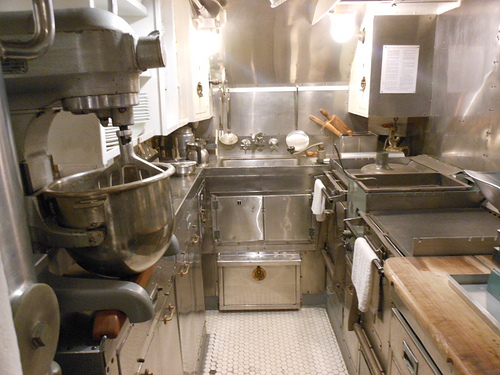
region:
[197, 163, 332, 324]
Part of a dirty kitchen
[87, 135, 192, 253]
A mixer in the kitchen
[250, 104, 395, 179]
Some silverware in the kitchen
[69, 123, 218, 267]
TO make food and drinks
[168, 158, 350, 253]
To keep things in the kitchen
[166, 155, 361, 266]
Good for storage here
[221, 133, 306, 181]
Used to wash dishes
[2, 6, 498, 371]
kitchen full of stainless steal appliances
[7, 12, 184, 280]
large stand mixer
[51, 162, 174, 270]
silver bowl of the mixer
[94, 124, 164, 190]
mixer in the silver bowl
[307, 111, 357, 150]
knife block on the counter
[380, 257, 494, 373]
wooden countertop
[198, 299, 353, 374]
white tile floor in the kitchen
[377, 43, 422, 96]
paper affixed to cabinet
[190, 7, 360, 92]
light reflecting on walls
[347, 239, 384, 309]
towel hanging from oven handle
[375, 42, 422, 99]
a paper hanging on a wall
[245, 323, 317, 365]
a tile floor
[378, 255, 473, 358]
a wood counter top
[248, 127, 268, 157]
a water faucet in a sink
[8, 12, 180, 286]
a large silver mixing bowl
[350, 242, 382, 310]
a white towel hanging on a handle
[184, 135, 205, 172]
a silver coffee pot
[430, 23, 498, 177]
metal back splash on a the wall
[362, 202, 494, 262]
a cooking griddle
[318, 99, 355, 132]
a wood rolling pin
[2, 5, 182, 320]
professional silver metal food mixer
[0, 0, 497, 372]
professional kitchen for baking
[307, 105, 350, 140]
two wooden rolling pins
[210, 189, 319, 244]
two silver metal doors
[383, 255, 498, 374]
light wood counter with drawer underneath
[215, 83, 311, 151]
utensils hanging on the wall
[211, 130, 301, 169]
silver faucet and sink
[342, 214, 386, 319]
white towel hanging from an oven handle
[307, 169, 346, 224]
small white towel hanging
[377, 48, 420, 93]
white paper with black typing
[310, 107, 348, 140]
wooden knife block on the counter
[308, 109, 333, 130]
handles of the knives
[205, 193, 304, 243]
cabinet doors underneath sink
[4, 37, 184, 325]
silver stand mixer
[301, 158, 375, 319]
stainless steel oven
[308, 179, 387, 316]
towels hanging from oven door handles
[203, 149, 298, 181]
stainless steel sink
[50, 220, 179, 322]
feet of the stainless steel stand mixer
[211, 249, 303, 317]
steel box in front of sink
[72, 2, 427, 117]
cabinets above countertops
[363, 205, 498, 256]
grill in the kitchen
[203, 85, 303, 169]
sink in the kitchen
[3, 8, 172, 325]
heavy duty mixer in the kitchen